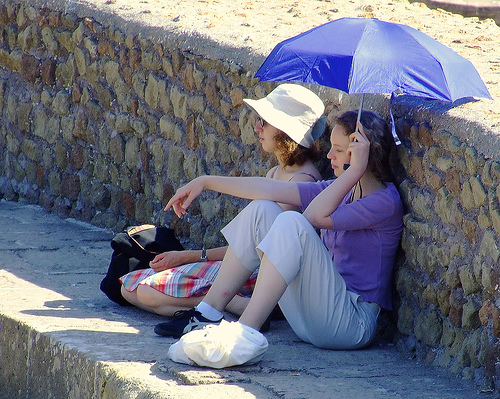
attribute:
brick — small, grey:
[163, 147, 190, 180]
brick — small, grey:
[453, 256, 474, 298]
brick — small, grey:
[407, 213, 435, 243]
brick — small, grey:
[188, 61, 208, 91]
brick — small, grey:
[458, 184, 477, 210]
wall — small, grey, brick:
[404, 110, 499, 377]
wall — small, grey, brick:
[26, 3, 242, 193]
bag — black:
[75, 194, 178, 273]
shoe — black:
[141, 294, 240, 345]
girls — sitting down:
[194, 103, 445, 359]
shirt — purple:
[282, 169, 417, 284]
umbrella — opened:
[257, 20, 493, 87]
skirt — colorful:
[135, 226, 272, 294]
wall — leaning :
[12, 9, 142, 219]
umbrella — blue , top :
[242, 9, 484, 139]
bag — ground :
[101, 208, 187, 325]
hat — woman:
[238, 76, 336, 156]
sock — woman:
[184, 300, 269, 350]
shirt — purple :
[290, 170, 407, 306]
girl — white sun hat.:
[119, 63, 309, 313]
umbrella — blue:
[266, 24, 475, 108]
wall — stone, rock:
[7, 10, 197, 174]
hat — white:
[236, 69, 319, 145]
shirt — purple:
[300, 180, 418, 277]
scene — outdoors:
[10, 11, 482, 394]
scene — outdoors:
[0, 9, 480, 363]